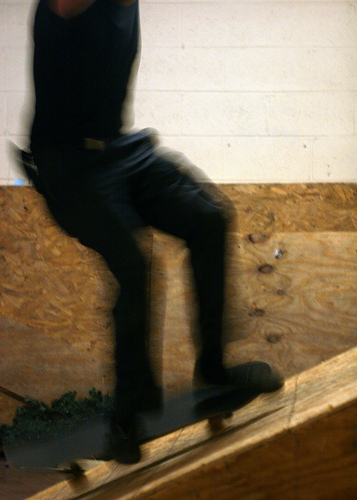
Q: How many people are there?
A: One.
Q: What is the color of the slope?
A: Brown.